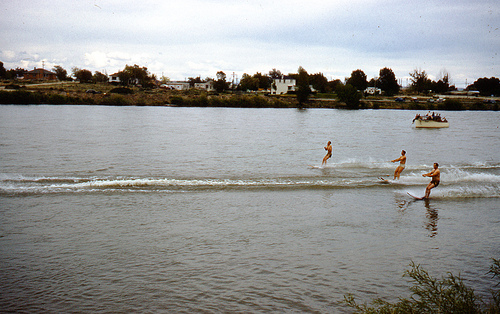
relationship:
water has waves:
[10, 100, 486, 292] [34, 151, 494, 204]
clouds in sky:
[20, 8, 369, 80] [2, 5, 493, 70]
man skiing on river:
[321, 139, 333, 169] [4, 107, 496, 311]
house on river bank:
[182, 74, 233, 106] [27, 72, 489, 107]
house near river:
[161, 75, 219, 91] [4, 107, 496, 311]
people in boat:
[411, 109, 447, 121] [414, 117, 449, 127]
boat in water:
[406, 109, 448, 129] [121, 125, 340, 154]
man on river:
[417, 162, 448, 197] [4, 107, 496, 311]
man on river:
[382, 151, 429, 191] [47, 162, 438, 285]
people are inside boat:
[411, 109, 447, 121] [410, 120, 450, 130]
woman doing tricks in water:
[319, 137, 332, 168] [1, 103, 497, 309]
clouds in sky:
[20, 8, 369, 80] [157, 23, 257, 61]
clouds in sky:
[20, 8, 369, 80] [82, 0, 479, 109]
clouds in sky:
[20, 8, 369, 80] [0, 0, 499, 90]